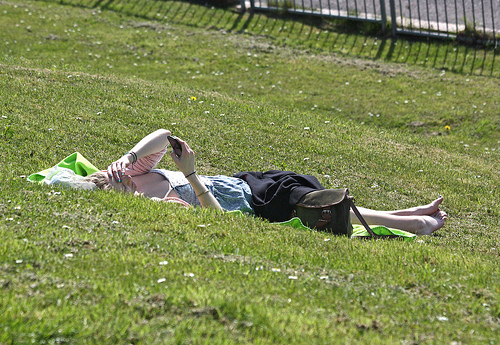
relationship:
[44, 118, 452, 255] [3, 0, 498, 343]
woman laying in grass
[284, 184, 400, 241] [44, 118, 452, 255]
bag next to woman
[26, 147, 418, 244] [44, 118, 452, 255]
towel under woman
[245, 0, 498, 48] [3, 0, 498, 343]
fence against grass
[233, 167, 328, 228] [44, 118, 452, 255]
jacket on woman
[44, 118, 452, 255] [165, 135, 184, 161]
woman holding cell phone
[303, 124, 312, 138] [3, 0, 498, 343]
flower in grass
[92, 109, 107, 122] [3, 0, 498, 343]
flower in grass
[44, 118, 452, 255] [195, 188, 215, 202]
woman wearing bracelet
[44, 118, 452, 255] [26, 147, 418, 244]
woman laying on towel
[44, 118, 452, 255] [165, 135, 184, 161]
woman looking at cell phone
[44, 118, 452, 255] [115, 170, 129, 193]
woman shading eyes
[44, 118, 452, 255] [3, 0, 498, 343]
woman on grass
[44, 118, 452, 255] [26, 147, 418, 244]
woman on towel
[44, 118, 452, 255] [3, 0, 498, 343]
woman lying on grass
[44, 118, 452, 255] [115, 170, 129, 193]
woman sheilding eyes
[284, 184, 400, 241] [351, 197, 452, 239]
bag near legs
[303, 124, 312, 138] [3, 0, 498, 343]
flower growing with grass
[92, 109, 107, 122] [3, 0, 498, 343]
flower growing with grass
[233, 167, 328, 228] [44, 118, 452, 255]
jacket covering woman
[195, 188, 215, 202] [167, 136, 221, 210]
bracelet on arm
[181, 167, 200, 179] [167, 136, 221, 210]
bracelet on arm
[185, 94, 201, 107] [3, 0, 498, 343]
flower in grass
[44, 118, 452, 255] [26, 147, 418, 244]
woman lying on towel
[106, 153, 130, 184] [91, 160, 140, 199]
hand touching head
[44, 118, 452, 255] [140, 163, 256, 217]
woman wearing tank top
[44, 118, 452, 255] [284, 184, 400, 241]
woman has bag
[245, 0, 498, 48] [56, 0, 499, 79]
fence casting shadow